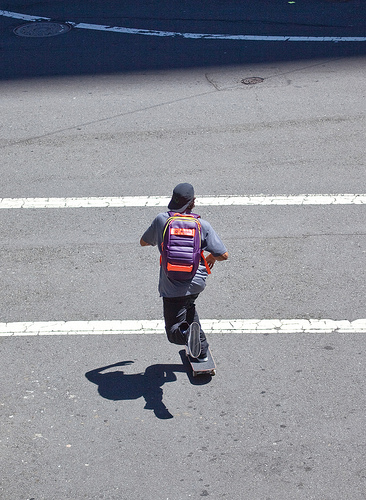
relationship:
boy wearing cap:
[140, 182, 229, 363] [167, 182, 194, 213]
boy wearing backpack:
[140, 182, 229, 363] [158, 211, 210, 282]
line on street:
[0, 169, 364, 224] [9, 171, 352, 244]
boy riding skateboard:
[140, 182, 229, 363] [177, 341, 218, 382]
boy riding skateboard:
[140, 182, 229, 363] [174, 337, 221, 383]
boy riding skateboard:
[141, 180, 231, 381] [174, 338, 223, 386]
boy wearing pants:
[140, 182, 229, 363] [159, 291, 207, 338]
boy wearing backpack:
[141, 180, 231, 381] [161, 211, 201, 282]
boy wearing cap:
[140, 182, 229, 363] [150, 176, 215, 253]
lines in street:
[0, 318, 366, 337] [3, 56, 362, 496]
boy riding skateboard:
[140, 182, 229, 363] [185, 345, 216, 378]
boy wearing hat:
[140, 182, 229, 363] [166, 182, 193, 213]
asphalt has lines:
[1, 0, 364, 498] [0, 8, 364, 43]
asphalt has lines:
[1, 0, 364, 498] [1, 191, 364, 207]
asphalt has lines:
[1, 0, 364, 498] [1, 318, 364, 337]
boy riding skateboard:
[140, 182, 229, 363] [148, 278, 246, 383]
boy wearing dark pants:
[140, 182, 229, 363] [160, 294, 210, 356]